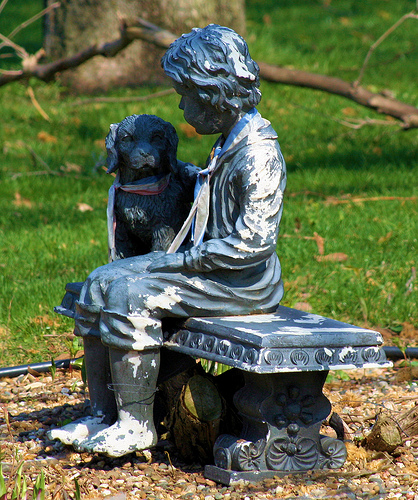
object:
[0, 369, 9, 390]
rocks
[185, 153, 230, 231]
ribbons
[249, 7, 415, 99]
area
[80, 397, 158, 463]
red hand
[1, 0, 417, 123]
branch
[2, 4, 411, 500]
ground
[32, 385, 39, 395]
stone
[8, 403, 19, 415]
stone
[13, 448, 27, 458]
stone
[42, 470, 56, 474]
stone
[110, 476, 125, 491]
stone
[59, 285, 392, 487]
bench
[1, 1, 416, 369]
grass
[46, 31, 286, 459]
boy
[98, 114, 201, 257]
dog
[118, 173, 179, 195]
collar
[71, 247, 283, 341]
pants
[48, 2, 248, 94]
tree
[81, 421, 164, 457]
paint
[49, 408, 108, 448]
paint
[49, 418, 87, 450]
foot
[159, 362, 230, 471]
trunk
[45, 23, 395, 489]
statue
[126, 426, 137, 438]
patches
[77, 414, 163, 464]
foot